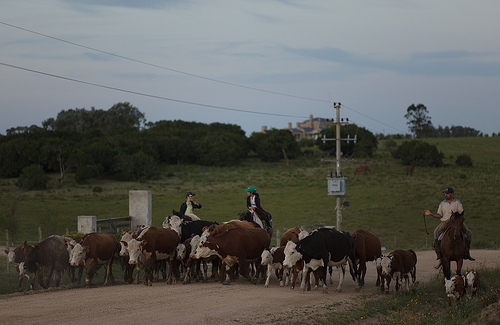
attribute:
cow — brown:
[16, 257, 37, 292]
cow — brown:
[373, 247, 418, 289]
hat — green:
[243, 185, 254, 194]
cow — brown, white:
[271, 206, 413, 313]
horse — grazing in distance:
[353, 162, 372, 178]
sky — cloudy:
[41, 17, 481, 125]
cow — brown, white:
[111, 229, 183, 289]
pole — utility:
[316, 99, 356, 236]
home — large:
[260, 114, 348, 141]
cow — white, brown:
[3, 234, 74, 291]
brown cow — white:
[116, 228, 144, 260]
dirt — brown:
[68, 280, 207, 323]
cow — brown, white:
[68, 230, 126, 287]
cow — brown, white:
[351, 230, 449, 298]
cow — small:
[371, 247, 422, 289]